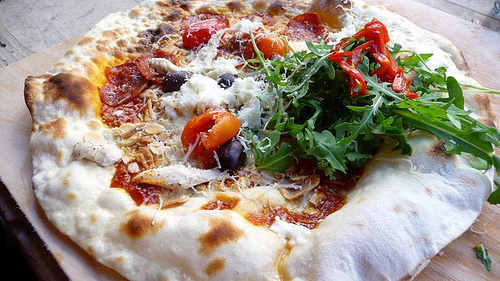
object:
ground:
[412, 200, 500, 281]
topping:
[250, 19, 460, 180]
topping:
[278, 173, 321, 201]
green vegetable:
[238, 21, 500, 206]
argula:
[241, 18, 499, 205]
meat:
[97, 62, 150, 108]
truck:
[190, 18, 500, 205]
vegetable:
[248, 17, 498, 204]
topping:
[100, 62, 153, 106]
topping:
[148, 57, 195, 92]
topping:
[181, 109, 241, 170]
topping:
[215, 140, 248, 171]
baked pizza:
[23, 0, 500, 281]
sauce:
[315, 185, 340, 212]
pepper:
[363, 16, 392, 74]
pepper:
[326, 49, 368, 100]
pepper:
[392, 68, 419, 101]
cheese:
[73, 19, 276, 191]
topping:
[244, 32, 290, 61]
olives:
[160, 70, 193, 93]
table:
[0, 0, 499, 281]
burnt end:
[24, 72, 98, 114]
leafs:
[357, 91, 444, 134]